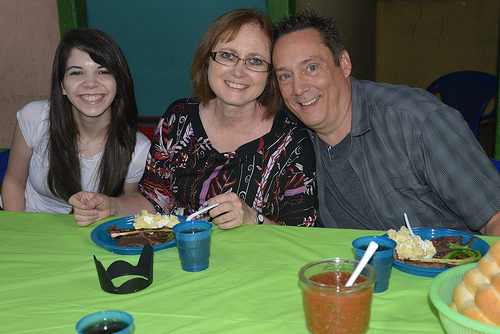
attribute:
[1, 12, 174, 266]
woman — wearing, smile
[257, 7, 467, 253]
man — wearing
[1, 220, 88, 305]
table — green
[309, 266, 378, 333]
bowl — salsa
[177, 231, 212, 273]
cup — blue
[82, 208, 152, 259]
plate — blue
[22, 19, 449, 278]
family — eating, having, celebrating, together, table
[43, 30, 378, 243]
everyone — smiling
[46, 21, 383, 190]
people — posing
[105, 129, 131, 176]
hair — dark, red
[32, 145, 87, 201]
shirt — white, sleeved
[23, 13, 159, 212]
lady — wearing, hold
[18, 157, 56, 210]
top — whiet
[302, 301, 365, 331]
salsa — jar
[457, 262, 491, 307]
bread — loaf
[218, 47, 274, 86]
eye — glasses, blue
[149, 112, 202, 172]
shirt — black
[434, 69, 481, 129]
chair — blue